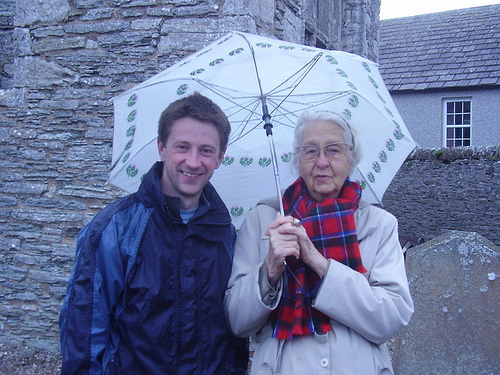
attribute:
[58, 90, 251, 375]
man — young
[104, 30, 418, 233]
umbrella — white, green, pink, open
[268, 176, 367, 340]
scarf — plaid, red, blue, black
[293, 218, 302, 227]
ring — metal, gaudy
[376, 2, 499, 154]
house — in background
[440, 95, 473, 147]
window — paned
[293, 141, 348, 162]
glasses — metal framed, retro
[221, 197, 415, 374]
jacket — tan, ecru colored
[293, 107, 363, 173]
hair — white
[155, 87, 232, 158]
hair — brown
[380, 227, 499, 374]
wall — stone, cement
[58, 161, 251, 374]
coat — blue, ecru